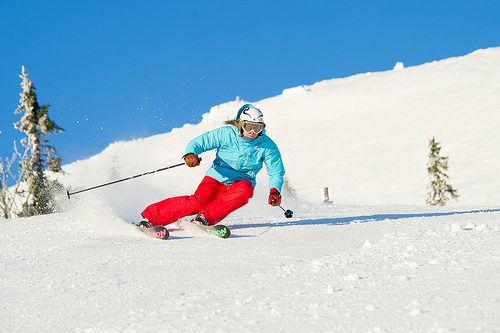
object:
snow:
[13, 48, 499, 325]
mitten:
[181, 152, 204, 167]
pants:
[139, 175, 257, 224]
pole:
[65, 153, 205, 201]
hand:
[182, 151, 202, 167]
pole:
[268, 197, 296, 220]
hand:
[266, 188, 284, 207]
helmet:
[235, 106, 264, 138]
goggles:
[237, 119, 266, 135]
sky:
[0, 1, 499, 191]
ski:
[139, 217, 172, 241]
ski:
[200, 217, 233, 240]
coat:
[186, 125, 283, 196]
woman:
[69, 104, 296, 239]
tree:
[426, 136, 462, 206]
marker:
[321, 185, 337, 205]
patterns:
[235, 105, 268, 122]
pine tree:
[1, 63, 70, 217]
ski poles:
[62, 154, 203, 201]